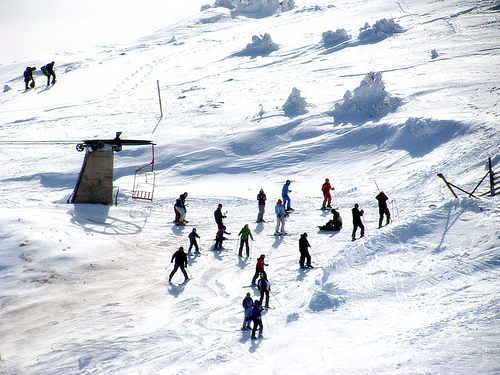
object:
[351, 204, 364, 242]
people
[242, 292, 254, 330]
skier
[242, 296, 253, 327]
blue outifit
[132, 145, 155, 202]
lift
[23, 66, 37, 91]
people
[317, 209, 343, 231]
person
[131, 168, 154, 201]
chair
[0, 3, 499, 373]
snow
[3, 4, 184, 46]
sky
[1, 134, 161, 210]
ski lift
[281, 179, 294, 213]
skier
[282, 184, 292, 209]
outfit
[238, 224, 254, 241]
jacket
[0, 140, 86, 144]
lift cable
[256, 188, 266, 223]
skier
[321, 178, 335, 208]
skier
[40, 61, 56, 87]
person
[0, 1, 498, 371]
hill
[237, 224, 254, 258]
person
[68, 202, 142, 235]
shadow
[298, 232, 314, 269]
person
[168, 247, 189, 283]
person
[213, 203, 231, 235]
person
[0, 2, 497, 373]
ground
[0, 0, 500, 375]
ski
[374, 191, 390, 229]
people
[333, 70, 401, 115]
bergs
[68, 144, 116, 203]
stone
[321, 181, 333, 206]
outfit